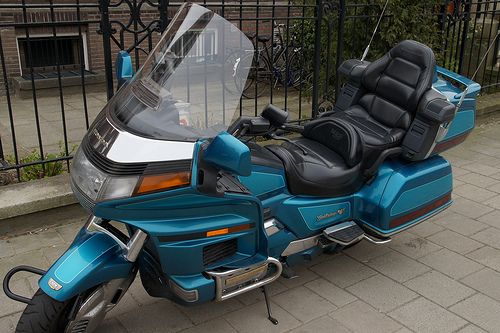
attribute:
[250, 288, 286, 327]
kickstand — black